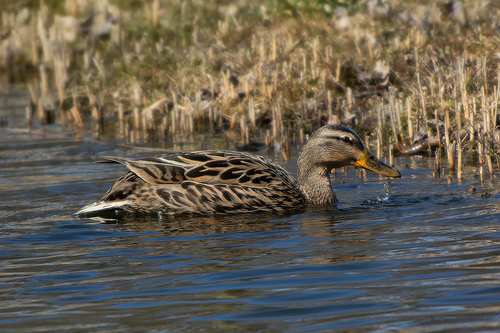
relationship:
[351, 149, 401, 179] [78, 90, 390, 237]
beak on duck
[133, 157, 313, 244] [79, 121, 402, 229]
feathers on duck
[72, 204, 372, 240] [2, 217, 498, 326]
reflection in water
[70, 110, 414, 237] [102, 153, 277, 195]
duck has feathers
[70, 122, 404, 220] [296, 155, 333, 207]
duck has neck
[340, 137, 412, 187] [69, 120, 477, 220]
beak of duck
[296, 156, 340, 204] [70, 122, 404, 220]
neck of duck